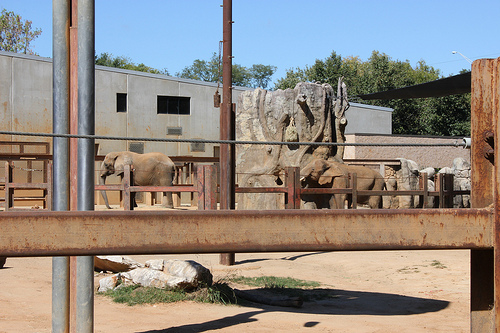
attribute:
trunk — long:
[100, 172, 112, 208]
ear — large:
[314, 160, 341, 185]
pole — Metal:
[2, 203, 497, 249]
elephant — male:
[102, 148, 178, 198]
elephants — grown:
[102, 154, 180, 208]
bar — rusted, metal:
[14, 203, 480, 253]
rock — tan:
[108, 258, 211, 294]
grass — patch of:
[112, 280, 238, 310]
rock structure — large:
[224, 65, 354, 208]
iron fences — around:
[22, 9, 495, 253]